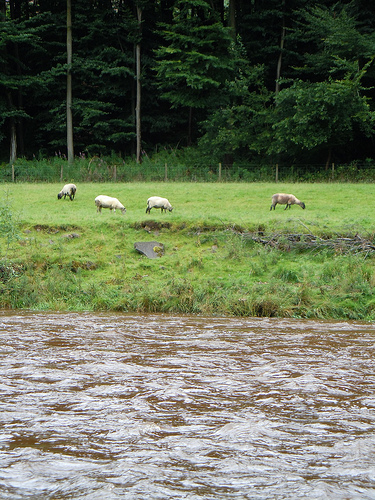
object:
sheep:
[146, 195, 174, 215]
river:
[73, 332, 120, 350]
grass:
[200, 190, 235, 213]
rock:
[133, 239, 163, 260]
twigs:
[208, 218, 302, 253]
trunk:
[134, 63, 142, 167]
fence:
[172, 161, 240, 188]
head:
[171, 204, 174, 212]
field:
[171, 254, 289, 285]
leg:
[149, 208, 151, 214]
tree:
[101, 7, 185, 163]